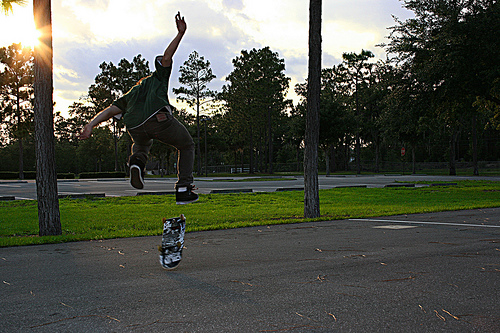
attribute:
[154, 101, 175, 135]
tag — brown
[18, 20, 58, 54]
sun — shining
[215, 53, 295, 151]
tree — green, filled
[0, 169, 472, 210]
parking lot — paved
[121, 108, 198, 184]
jeans — pair, men's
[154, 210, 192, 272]
skateboard — black, white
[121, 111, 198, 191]
jeans — nlack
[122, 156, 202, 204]
shoes — black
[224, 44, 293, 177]
tree — large, green, distant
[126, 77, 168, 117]
tshirt — green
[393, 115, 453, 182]
ground — grass, long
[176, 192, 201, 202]
shoe — black, white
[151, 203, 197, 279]
skateboard — upside down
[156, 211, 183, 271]
skateboard — black, white, upside down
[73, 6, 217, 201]
man — soaring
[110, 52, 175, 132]
shirt — green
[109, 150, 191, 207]
shoes — black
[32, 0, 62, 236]
trunk — tall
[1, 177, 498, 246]
median — grassy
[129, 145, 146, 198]
shoe — white, black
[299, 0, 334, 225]
tree trunk — tall, thin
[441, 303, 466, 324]
sticks — brown